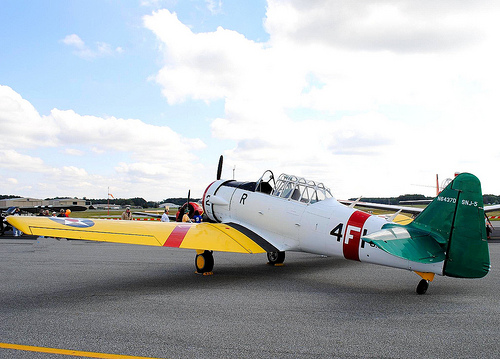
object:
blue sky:
[0, 0, 265, 140]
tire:
[416, 278, 429, 294]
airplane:
[132, 189, 204, 222]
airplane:
[339, 200, 499, 214]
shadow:
[0, 256, 475, 319]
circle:
[47, 217, 95, 228]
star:
[50, 217, 89, 227]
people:
[0, 207, 70, 242]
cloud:
[0, 0, 496, 194]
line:
[0, 342, 164, 359]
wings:
[361, 227, 447, 264]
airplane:
[4, 154, 491, 295]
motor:
[205, 179, 236, 224]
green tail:
[359, 171, 493, 279]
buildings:
[0, 197, 98, 212]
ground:
[0, 233, 498, 356]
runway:
[0, 233, 500, 355]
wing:
[4, 214, 276, 254]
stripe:
[162, 223, 193, 247]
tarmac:
[0, 232, 499, 355]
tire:
[195, 250, 214, 273]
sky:
[0, 0, 500, 201]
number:
[330, 222, 344, 242]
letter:
[345, 225, 362, 245]